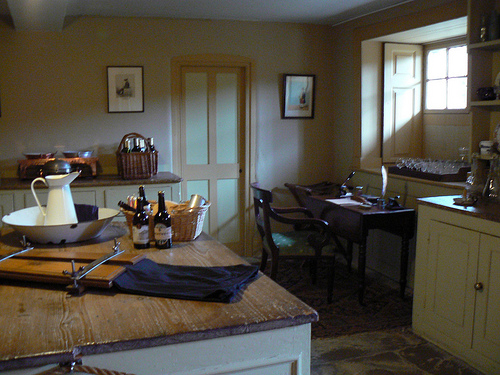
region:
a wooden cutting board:
[11, 236, 161, 291]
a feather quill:
[368, 163, 392, 212]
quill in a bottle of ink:
[372, 160, 392, 215]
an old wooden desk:
[246, 167, 415, 313]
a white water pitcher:
[6, 167, 126, 247]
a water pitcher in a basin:
[5, 164, 140, 250]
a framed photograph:
[90, 48, 166, 129]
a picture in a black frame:
[273, 57, 333, 131]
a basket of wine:
[107, 120, 169, 182]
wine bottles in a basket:
[108, 114, 174, 184]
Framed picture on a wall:
[99, 56, 153, 119]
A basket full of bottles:
[111, 125, 165, 187]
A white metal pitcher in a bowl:
[25, 168, 86, 235]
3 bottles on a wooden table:
[119, 181, 183, 256]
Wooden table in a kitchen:
[285, 161, 419, 315]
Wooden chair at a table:
[244, 179, 353, 302]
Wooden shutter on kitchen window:
[376, 39, 425, 170]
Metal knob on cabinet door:
[463, 273, 490, 295]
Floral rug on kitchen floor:
[375, 337, 415, 364]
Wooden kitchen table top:
[83, 302, 150, 328]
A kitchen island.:
[0, 208, 325, 370]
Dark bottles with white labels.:
[130, 182, 172, 249]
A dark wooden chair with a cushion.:
[247, 184, 338, 304]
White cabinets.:
[414, 203, 498, 372]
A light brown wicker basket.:
[119, 201, 209, 241]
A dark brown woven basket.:
[118, 134, 160, 178]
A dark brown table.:
[304, 187, 412, 307]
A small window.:
[424, 52, 469, 116]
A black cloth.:
[107, 260, 262, 305]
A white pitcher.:
[30, 168, 87, 227]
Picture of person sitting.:
[105, 60, 146, 118]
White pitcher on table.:
[27, 167, 76, 220]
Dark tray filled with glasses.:
[387, 153, 460, 182]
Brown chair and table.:
[250, 169, 415, 303]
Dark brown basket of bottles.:
[111, 128, 161, 179]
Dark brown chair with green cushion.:
[250, 172, 343, 297]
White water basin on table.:
[1, 202, 124, 249]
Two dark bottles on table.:
[127, 194, 176, 249]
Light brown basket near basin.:
[121, 183, 211, 241]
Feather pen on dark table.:
[375, 158, 389, 210]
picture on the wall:
[102, 59, 147, 119]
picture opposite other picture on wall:
[277, 71, 319, 122]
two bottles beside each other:
[132, 189, 177, 249]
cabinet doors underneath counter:
[412, 210, 498, 367]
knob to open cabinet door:
[469, 280, 486, 292]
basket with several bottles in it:
[114, 128, 161, 180]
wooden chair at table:
[247, 180, 341, 292]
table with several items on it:
[310, 162, 412, 299]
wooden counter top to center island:
[8, 296, 165, 339]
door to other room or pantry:
[167, 49, 254, 251]